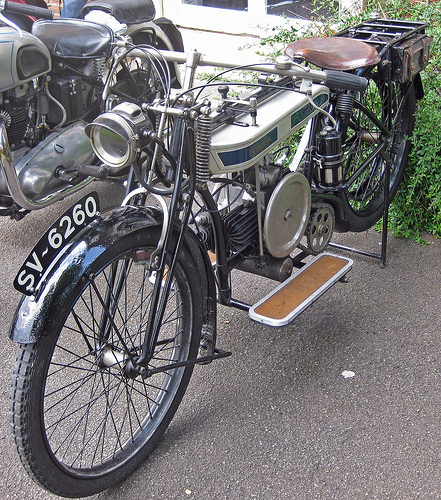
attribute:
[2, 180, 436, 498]
ground — grey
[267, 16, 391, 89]
seat — brown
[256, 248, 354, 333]
step — tan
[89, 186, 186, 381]
frame — black 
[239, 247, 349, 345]
stool — brown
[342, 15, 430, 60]
spot — black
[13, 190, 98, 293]
numbers — white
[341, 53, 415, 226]
rubber wheel — black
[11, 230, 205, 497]
rubber wheel — black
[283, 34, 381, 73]
seat — brown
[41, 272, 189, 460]
spokes — black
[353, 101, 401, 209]
spokes — black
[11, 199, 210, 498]
wheel — black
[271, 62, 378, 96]
handle — black